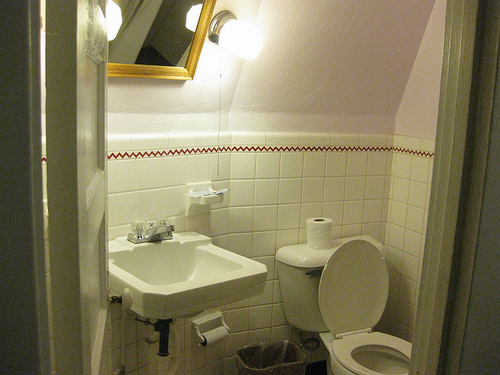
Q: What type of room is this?
A: It is a bathroom.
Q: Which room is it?
A: It is a bathroom.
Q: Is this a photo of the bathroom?
A: Yes, it is showing the bathroom.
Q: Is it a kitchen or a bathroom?
A: It is a bathroom.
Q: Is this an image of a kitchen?
A: No, the picture is showing a bathroom.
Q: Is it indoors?
A: Yes, it is indoors.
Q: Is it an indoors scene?
A: Yes, it is indoors.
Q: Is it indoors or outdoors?
A: It is indoors.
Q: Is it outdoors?
A: No, it is indoors.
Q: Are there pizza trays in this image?
A: No, there are no pizza trays.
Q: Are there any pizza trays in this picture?
A: No, there are no pizza trays.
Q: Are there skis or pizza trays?
A: No, there are no pizza trays or skis.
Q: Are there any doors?
A: Yes, there is a door.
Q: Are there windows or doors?
A: Yes, there is a door.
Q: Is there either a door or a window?
A: Yes, there is a door.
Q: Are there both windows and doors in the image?
A: No, there is a door but no windows.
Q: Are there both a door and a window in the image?
A: No, there is a door but no windows.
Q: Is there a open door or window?
A: Yes, there is an open door.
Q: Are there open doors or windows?
A: Yes, there is an open door.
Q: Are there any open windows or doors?
A: Yes, there is an open door.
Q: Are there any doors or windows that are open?
A: Yes, the door is open.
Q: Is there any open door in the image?
A: Yes, there is an open door.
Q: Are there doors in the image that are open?
A: Yes, there is a door that is open.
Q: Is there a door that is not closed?
A: Yes, there is a open door.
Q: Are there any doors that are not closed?
A: Yes, there is a open door.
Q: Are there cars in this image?
A: No, there are no cars.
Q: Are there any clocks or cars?
A: No, there are no cars or clocks.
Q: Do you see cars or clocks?
A: No, there are no cars or clocks.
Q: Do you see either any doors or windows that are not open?
A: No, there is a door but it is open.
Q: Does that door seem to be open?
A: Yes, the door is open.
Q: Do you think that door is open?
A: Yes, the door is open.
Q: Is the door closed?
A: No, the door is open.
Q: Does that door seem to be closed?
A: No, the door is open.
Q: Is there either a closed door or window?
A: No, there is a door but it is open.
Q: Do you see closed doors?
A: No, there is a door but it is open.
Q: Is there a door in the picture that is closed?
A: No, there is a door but it is open.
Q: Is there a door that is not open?
A: No, there is a door but it is open.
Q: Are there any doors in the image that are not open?
A: No, there is a door but it is open.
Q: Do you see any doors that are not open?
A: No, there is a door but it is open.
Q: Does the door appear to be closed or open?
A: The door is open.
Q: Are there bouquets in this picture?
A: No, there are no bouquets.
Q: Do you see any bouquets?
A: No, there are no bouquets.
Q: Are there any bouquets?
A: No, there are no bouquets.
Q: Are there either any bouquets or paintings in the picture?
A: No, there are no bouquets or paintings.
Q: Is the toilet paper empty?
A: Yes, the toilet paper is empty.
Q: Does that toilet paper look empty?
A: Yes, the toilet paper is empty.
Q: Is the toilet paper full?
A: No, the toilet paper is empty.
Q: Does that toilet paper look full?
A: No, the toilet paper is empty.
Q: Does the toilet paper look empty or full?
A: The toilet paper is empty.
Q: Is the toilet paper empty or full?
A: The toilet paper is empty.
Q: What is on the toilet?
A: The toilet paper is on the toilet.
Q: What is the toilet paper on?
A: The toilet paper is on the toilet.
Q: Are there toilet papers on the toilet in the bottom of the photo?
A: Yes, there is a toilet paper on the toilet.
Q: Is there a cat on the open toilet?
A: No, there is a toilet paper on the toilet.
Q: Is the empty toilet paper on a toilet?
A: Yes, the toilet paper is on a toilet.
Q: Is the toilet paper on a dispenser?
A: No, the toilet paper is on a toilet.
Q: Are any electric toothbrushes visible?
A: No, there are no electric toothbrushes.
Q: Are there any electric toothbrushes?
A: No, there are no electric toothbrushes.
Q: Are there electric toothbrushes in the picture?
A: No, there are no electric toothbrushes.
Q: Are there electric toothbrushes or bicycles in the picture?
A: No, there are no electric toothbrushes or bicycles.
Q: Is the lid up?
A: Yes, the lid is up.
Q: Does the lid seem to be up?
A: Yes, the lid is up.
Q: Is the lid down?
A: No, the lid is up.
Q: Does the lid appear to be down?
A: No, the lid is up.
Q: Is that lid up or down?
A: The lid is up.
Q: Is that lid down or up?
A: The lid is up.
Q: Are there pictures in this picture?
A: No, there are no pictures.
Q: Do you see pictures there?
A: No, there are no pictures.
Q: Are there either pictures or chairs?
A: No, there are no pictures or chairs.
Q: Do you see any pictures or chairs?
A: No, there are no pictures or chairs.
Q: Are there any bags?
A: Yes, there is a bag.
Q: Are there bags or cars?
A: Yes, there is a bag.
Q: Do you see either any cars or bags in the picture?
A: Yes, there is a bag.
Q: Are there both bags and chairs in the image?
A: No, there is a bag but no chairs.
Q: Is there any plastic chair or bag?
A: Yes, there is a plastic bag.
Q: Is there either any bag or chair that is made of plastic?
A: Yes, the bag is made of plastic.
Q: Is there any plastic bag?
A: Yes, there is a bag that is made of plastic.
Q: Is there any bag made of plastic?
A: Yes, there is a bag that is made of plastic.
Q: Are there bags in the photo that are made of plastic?
A: Yes, there is a bag that is made of plastic.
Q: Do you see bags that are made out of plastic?
A: Yes, there is a bag that is made of plastic.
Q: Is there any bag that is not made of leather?
A: Yes, there is a bag that is made of plastic.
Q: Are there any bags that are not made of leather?
A: Yes, there is a bag that is made of plastic.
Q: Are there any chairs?
A: No, there are no chairs.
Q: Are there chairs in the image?
A: No, there are no chairs.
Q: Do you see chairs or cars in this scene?
A: No, there are no chairs or cars.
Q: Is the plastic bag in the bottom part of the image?
A: Yes, the bag is in the bottom of the image.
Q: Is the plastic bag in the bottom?
A: Yes, the bag is in the bottom of the image.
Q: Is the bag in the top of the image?
A: No, the bag is in the bottom of the image.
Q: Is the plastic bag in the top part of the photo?
A: No, the bag is in the bottom of the image.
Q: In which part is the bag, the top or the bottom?
A: The bag is in the bottom of the image.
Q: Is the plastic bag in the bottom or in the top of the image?
A: The bag is in the bottom of the image.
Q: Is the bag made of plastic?
A: Yes, the bag is made of plastic.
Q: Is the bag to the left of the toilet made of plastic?
A: Yes, the bag is made of plastic.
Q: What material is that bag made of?
A: The bag is made of plastic.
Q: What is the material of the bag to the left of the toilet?
A: The bag is made of plastic.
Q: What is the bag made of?
A: The bag is made of plastic.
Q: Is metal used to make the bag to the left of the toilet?
A: No, the bag is made of plastic.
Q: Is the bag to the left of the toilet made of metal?
A: No, the bag is made of plastic.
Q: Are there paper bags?
A: No, there is a bag but it is made of plastic.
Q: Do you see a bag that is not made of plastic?
A: No, there is a bag but it is made of plastic.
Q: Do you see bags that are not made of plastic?
A: No, there is a bag but it is made of plastic.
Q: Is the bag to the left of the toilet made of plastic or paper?
A: The bag is made of plastic.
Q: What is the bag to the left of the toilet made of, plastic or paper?
A: The bag is made of plastic.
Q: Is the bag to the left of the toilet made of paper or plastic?
A: The bag is made of plastic.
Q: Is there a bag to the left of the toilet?
A: Yes, there is a bag to the left of the toilet.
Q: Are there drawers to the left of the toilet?
A: No, there is a bag to the left of the toilet.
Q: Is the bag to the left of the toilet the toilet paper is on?
A: Yes, the bag is to the left of the toilet.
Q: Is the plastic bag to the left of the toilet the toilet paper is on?
A: Yes, the bag is to the left of the toilet.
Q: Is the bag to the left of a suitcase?
A: No, the bag is to the left of the toilet.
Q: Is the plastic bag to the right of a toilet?
A: No, the bag is to the left of a toilet.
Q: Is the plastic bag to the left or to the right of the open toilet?
A: The bag is to the left of the toilet.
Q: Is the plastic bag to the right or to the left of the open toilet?
A: The bag is to the left of the toilet.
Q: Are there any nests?
A: No, there are no nests.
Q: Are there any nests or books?
A: No, there are no nests or books.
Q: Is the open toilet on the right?
A: Yes, the toilet is on the right of the image.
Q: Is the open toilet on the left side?
A: No, the toilet is on the right of the image.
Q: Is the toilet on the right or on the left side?
A: The toilet is on the right of the image.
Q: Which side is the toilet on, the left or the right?
A: The toilet is on the right of the image.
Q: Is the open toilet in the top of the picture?
A: No, the toilet is in the bottom of the image.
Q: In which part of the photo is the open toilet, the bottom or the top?
A: The toilet is in the bottom of the image.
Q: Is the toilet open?
A: Yes, the toilet is open.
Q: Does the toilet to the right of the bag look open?
A: Yes, the toilet is open.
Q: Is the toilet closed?
A: No, the toilet is open.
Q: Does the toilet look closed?
A: No, the toilet is open.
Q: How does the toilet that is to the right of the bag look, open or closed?
A: The toilet is open.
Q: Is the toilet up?
A: Yes, the toilet is up.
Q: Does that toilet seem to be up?
A: Yes, the toilet is up.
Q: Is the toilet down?
A: No, the toilet is up.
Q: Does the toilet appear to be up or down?
A: The toilet is up.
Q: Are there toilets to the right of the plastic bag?
A: Yes, there is a toilet to the right of the bag.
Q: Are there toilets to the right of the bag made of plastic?
A: Yes, there is a toilet to the right of the bag.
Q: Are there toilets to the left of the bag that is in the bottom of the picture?
A: No, the toilet is to the right of the bag.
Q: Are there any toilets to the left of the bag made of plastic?
A: No, the toilet is to the right of the bag.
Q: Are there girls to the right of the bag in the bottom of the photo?
A: No, there is a toilet to the right of the bag.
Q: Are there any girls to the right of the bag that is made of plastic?
A: No, there is a toilet to the right of the bag.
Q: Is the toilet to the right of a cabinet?
A: No, the toilet is to the right of the bag.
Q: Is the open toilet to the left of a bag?
A: No, the toilet is to the right of a bag.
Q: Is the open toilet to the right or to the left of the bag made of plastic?
A: The toilet is to the right of the bag.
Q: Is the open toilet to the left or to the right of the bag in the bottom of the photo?
A: The toilet is to the right of the bag.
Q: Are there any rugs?
A: No, there are no rugs.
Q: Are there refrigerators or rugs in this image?
A: No, there are no rugs or refrigerators.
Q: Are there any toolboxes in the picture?
A: No, there are no toolboxes.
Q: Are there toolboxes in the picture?
A: No, there are no toolboxes.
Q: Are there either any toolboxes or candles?
A: No, there are no toolboxes or candles.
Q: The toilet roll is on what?
A: The toilet roll is on the wall.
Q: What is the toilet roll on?
A: The toilet roll is on the wall.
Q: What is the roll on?
A: The toilet roll is on the wall.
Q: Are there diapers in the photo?
A: No, there are no diapers.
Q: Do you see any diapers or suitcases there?
A: No, there are no diapers or suitcases.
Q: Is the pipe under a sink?
A: Yes, the pipe is under a sink.